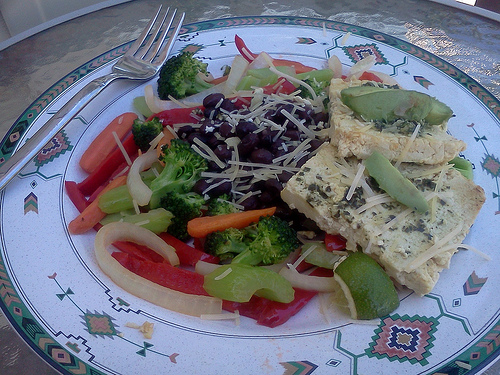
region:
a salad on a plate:
[72, 38, 484, 318]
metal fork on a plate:
[0, 6, 189, 189]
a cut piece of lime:
[330, 250, 399, 317]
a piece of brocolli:
[230, 218, 295, 268]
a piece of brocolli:
[153, 142, 199, 197]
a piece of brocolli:
[157, 55, 212, 95]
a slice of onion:
[92, 220, 220, 322]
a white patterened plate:
[0, 18, 499, 373]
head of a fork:
[114, 5, 193, 82]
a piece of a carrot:
[185, 207, 275, 239]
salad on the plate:
[118, 70, 396, 354]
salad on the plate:
[48, 113, 198, 311]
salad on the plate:
[151, 153, 306, 336]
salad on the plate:
[181, 15, 318, 182]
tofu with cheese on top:
[293, 121, 406, 312]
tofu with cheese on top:
[346, 80, 481, 196]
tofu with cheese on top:
[416, 130, 493, 210]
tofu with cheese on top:
[308, 61, 426, 166]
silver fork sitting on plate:
[7, 12, 180, 186]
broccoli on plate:
[130, 47, 289, 267]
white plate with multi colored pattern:
[0, 21, 499, 373]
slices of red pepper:
[82, 101, 327, 318]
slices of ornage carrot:
[76, 105, 278, 246]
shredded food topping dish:
[186, 76, 318, 196]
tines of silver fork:
[132, 1, 178, 73]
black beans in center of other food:
[188, 93, 313, 190]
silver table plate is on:
[15, 4, 480, 374]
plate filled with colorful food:
[10, 24, 467, 371]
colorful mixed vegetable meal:
[66, 37, 481, 315]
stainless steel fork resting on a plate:
[5, 5, 191, 206]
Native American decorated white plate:
[1, 4, 494, 370]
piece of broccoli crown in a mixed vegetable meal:
[150, 52, 214, 99]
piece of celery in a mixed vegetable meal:
[201, 264, 299, 309]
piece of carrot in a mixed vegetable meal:
[73, 112, 139, 173]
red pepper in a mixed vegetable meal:
[109, 239, 206, 294]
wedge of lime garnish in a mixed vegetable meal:
[324, 254, 403, 323]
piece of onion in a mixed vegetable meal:
[88, 219, 222, 320]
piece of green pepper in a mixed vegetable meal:
[341, 82, 452, 132]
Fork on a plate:
[59, 45, 164, 151]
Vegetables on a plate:
[73, 126, 281, 265]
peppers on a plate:
[103, 186, 216, 288]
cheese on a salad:
[213, 105, 328, 204]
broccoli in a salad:
[164, 51, 209, 96]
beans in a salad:
[223, 120, 309, 200]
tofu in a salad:
[283, 138, 472, 268]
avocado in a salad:
[352, 66, 478, 127]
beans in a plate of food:
[175, 73, 367, 258]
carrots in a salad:
[93, 120, 124, 209]